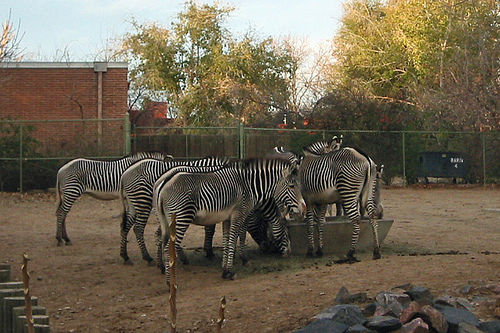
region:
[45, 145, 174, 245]
zebra eating at the metal bin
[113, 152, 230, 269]
zebra eating at the metal bin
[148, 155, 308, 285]
zebra eating at the metal bin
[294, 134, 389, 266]
zebra eating at the metal bin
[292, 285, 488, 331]
grey rocks by the zebras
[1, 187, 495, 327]
brown dirt the zebras are one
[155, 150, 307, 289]
zebra standing on dirt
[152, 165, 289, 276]
zebra standing on dirt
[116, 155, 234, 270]
zebra standing on dirt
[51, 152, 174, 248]
zebra standing on dirt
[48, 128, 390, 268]
zebras standing on dirt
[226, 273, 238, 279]
black colored zebra hoof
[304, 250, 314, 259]
black colored zebra hoof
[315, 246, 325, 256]
black colored zebra hoof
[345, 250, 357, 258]
black colored zebra hoof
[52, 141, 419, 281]
black and white striped zebras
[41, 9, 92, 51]
whtie clouds in blue sky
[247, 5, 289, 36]
whtie clouds in blue sky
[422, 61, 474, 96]
green and yellow leaves in trees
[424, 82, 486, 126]
green and yellow leaves in trees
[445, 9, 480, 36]
green and yellow leaves in trees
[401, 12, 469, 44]
green and yellow leaves in trees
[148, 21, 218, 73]
green and yellow leaves in trees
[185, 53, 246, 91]
green and yellow leaves in trees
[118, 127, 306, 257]
black and white zebras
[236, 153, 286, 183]
black and white mane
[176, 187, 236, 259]
black and white legs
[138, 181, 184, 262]
zebra has white tail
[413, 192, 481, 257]
ground is light brown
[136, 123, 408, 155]
grey fence behind zebras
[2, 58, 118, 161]
building is red brick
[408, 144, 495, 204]
blue bin behind fence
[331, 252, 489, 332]
grey rocks near zebras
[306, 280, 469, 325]
a pile of rocks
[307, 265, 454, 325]
a pile of rocks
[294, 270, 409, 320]
a pile of rocks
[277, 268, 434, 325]
a pile of rocks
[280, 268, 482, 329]
a pile of rocks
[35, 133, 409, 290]
the zebras have stripes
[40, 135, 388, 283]
the zebras have stripes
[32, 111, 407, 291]
the zebras have stripes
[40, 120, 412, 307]
the zebras have stripes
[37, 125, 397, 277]
the zebras have stripes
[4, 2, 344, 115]
blue of daytime sky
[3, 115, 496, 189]
poles of chain link fence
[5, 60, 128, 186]
brick wall of building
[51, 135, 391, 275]
cluster of zebras around troth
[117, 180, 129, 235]
tail with black tip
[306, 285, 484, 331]
pile of gray rocks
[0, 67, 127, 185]
red brick building wall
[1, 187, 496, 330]
dirt surface of zoo enclosure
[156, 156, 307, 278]
zebra is standing outside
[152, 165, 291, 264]
zebra is standing outside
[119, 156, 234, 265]
zebra is standing outside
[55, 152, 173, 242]
zebra is standing outside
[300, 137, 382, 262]
zebra is standing outside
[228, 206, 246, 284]
zebra has a leg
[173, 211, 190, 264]
zebra has a leg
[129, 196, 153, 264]
zebra has a leg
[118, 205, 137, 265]
zebra has a leg